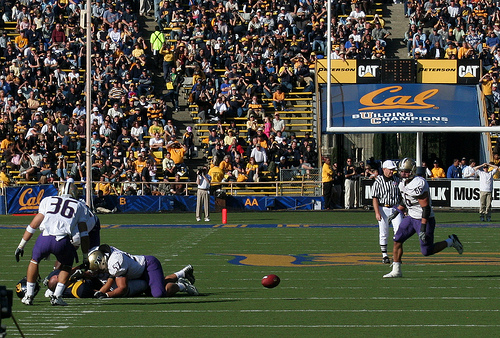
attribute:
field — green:
[227, 226, 393, 327]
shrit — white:
[394, 181, 436, 215]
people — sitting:
[99, 49, 273, 117]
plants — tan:
[371, 209, 405, 250]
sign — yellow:
[362, 72, 450, 131]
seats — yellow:
[301, 109, 309, 128]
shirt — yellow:
[211, 160, 228, 191]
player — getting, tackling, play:
[378, 161, 445, 292]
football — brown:
[248, 261, 294, 293]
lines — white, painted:
[293, 288, 349, 316]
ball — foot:
[256, 255, 288, 285]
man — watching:
[249, 139, 270, 163]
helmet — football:
[382, 150, 426, 185]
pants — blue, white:
[393, 226, 440, 252]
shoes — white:
[360, 249, 414, 288]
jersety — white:
[48, 196, 85, 231]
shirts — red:
[48, 26, 66, 47]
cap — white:
[376, 149, 402, 175]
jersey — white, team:
[43, 186, 91, 233]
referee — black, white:
[368, 158, 401, 261]